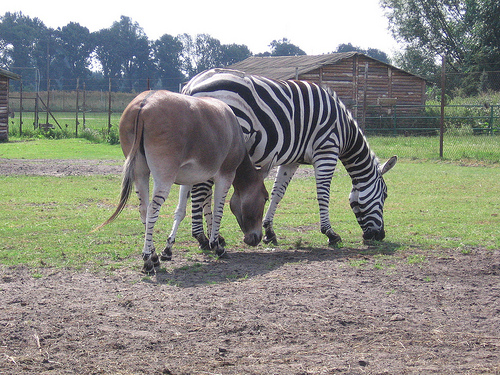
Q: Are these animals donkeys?
A: No, they are donkeys and zebras.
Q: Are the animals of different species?
A: Yes, they are donkeys and zebras.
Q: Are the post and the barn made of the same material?
A: Yes, both the post and the barn are made of wood.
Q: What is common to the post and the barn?
A: The material, both the post and the barn are wooden.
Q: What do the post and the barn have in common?
A: The material, both the post and the barn are wooden.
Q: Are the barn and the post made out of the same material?
A: Yes, both the barn and the post are made of wood.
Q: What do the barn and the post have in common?
A: The material, both the barn and the post are wooden.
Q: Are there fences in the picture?
A: Yes, there is a fence.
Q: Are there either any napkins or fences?
A: Yes, there is a fence.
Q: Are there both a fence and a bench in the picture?
A: No, there is a fence but no benches.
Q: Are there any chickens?
A: No, there are no chickens.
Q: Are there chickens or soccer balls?
A: No, there are no chickens or soccer balls.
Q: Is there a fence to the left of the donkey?
A: Yes, there is a fence to the left of the donkey.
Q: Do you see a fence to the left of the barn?
A: Yes, there is a fence to the left of the barn.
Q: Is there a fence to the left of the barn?
A: Yes, there is a fence to the left of the barn.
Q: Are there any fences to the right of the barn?
A: No, the fence is to the left of the barn.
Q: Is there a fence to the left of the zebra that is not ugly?
A: Yes, there is a fence to the left of the zebra.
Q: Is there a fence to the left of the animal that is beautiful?
A: Yes, there is a fence to the left of the zebra.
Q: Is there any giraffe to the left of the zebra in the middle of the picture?
A: No, there is a fence to the left of the zebra.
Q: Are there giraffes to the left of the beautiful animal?
A: No, there is a fence to the left of the zebra.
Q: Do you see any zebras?
A: Yes, there is a zebra.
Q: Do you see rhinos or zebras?
A: Yes, there is a zebra.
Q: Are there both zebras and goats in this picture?
A: No, there is a zebra but no goats.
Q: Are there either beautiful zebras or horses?
A: Yes, there is a beautiful zebra.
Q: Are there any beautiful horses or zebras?
A: Yes, there is a beautiful zebra.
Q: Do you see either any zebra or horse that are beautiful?
A: Yes, the zebra is beautiful.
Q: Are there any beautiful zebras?
A: Yes, there is a beautiful zebra.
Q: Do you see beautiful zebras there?
A: Yes, there is a beautiful zebra.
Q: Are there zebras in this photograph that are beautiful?
A: Yes, there is a zebra that is beautiful.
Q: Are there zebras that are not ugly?
A: Yes, there is an beautiful zebra.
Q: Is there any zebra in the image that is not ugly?
A: Yes, there is an beautiful zebra.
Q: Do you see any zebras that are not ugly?
A: Yes, there is an beautiful zebra.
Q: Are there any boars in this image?
A: No, there are no boars.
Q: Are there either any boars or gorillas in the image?
A: No, there are no boars or gorillas.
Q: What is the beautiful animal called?
A: The animal is a zebra.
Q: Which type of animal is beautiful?
A: The animal is a zebra.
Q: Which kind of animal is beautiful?
A: The animal is a zebra.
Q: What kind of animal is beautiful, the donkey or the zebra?
A: The zebra is beautiful.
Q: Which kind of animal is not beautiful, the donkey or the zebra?
A: The donkey is not beautiful.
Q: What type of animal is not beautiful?
A: The animal is a donkey.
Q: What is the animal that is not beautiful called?
A: The animal is a donkey.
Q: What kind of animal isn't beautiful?
A: The animal is a donkey.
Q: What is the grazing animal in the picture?
A: The animal is a zebra.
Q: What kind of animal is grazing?
A: The animal is a zebra.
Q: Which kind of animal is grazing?
A: The animal is a zebra.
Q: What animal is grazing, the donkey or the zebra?
A: The zebra is grazing.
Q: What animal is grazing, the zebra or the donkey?
A: The zebra is grazing.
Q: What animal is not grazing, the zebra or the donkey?
A: The donkey is not grazing.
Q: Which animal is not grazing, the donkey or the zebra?
A: The donkey is not grazing.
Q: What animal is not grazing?
A: The animal is a donkey.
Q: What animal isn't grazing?
A: The animal is a donkey.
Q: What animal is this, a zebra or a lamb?
A: This is a zebra.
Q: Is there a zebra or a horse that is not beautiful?
A: No, there is a zebra but it is beautiful.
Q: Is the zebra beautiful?
A: Yes, the zebra is beautiful.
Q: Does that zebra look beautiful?
A: Yes, the zebra is beautiful.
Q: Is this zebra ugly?
A: No, the zebra is beautiful.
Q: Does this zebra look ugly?
A: No, the zebra is beautiful.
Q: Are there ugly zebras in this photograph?
A: No, there is a zebra but it is beautiful.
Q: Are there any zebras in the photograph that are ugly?
A: No, there is a zebra but it is beautiful.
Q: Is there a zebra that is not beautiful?
A: No, there is a zebra but it is beautiful.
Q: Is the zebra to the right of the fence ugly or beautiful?
A: The zebra is beautiful.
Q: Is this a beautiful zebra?
A: Yes, this is a beautiful zebra.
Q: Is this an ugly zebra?
A: No, this is a beautiful zebra.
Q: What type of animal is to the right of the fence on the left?
A: The animal is a zebra.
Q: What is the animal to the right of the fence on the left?
A: The animal is a zebra.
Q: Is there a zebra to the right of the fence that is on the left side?
A: Yes, there is a zebra to the right of the fence.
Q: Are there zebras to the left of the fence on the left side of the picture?
A: No, the zebra is to the right of the fence.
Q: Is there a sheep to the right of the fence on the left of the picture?
A: No, there is a zebra to the right of the fence.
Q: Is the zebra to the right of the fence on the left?
A: Yes, the zebra is to the right of the fence.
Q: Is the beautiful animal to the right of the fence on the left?
A: Yes, the zebra is to the right of the fence.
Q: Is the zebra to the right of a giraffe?
A: No, the zebra is to the right of the fence.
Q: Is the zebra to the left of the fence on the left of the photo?
A: No, the zebra is to the right of the fence.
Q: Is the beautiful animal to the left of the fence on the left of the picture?
A: No, the zebra is to the right of the fence.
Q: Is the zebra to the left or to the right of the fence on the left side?
A: The zebra is to the right of the fence.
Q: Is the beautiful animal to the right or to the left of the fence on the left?
A: The zebra is to the right of the fence.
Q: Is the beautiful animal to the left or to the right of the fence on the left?
A: The zebra is to the right of the fence.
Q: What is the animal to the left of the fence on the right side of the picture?
A: The animal is a zebra.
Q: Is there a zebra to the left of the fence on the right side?
A: Yes, there is a zebra to the left of the fence.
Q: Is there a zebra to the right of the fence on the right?
A: No, the zebra is to the left of the fence.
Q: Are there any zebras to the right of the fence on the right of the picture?
A: No, the zebra is to the left of the fence.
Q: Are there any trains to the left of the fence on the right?
A: No, there is a zebra to the left of the fence.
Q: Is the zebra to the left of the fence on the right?
A: Yes, the zebra is to the left of the fence.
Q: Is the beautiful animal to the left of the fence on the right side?
A: Yes, the zebra is to the left of the fence.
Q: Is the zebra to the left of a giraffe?
A: No, the zebra is to the left of the fence.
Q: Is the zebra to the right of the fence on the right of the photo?
A: No, the zebra is to the left of the fence.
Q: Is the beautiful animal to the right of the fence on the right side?
A: No, the zebra is to the left of the fence.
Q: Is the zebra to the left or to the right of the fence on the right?
A: The zebra is to the left of the fence.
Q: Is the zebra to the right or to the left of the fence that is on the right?
A: The zebra is to the left of the fence.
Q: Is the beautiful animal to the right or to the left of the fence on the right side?
A: The zebra is to the left of the fence.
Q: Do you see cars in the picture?
A: No, there are no cars.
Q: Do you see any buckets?
A: No, there are no buckets.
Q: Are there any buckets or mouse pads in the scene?
A: No, there are no buckets or mouse pads.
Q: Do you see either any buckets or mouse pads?
A: No, there are no buckets or mouse pads.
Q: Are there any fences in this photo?
A: Yes, there is a fence.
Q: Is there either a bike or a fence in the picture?
A: Yes, there is a fence.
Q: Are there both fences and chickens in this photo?
A: No, there is a fence but no chickens.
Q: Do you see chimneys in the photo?
A: No, there are no chimneys.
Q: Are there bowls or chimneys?
A: No, there are no chimneys or bowls.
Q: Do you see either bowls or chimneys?
A: No, there are no chimneys or bowls.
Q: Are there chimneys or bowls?
A: No, there are no chimneys or bowls.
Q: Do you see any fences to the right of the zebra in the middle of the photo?
A: Yes, there is a fence to the right of the zebra.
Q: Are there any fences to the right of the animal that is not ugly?
A: Yes, there is a fence to the right of the zebra.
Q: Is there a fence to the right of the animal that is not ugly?
A: Yes, there is a fence to the right of the zebra.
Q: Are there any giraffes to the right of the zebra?
A: No, there is a fence to the right of the zebra.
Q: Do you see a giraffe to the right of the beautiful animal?
A: No, there is a fence to the right of the zebra.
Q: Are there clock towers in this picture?
A: No, there are no clock towers.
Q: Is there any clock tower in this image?
A: No, there are no clock towers.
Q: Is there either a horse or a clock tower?
A: No, there are no clock towers or horses.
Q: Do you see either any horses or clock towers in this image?
A: No, there are no clock towers or horses.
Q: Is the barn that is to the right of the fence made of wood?
A: Yes, the barn is made of wood.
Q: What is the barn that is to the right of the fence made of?
A: The barn is made of wood.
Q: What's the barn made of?
A: The barn is made of wood.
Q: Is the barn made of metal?
A: No, the barn is made of wood.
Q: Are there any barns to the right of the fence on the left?
A: Yes, there is a barn to the right of the fence.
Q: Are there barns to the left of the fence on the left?
A: No, the barn is to the right of the fence.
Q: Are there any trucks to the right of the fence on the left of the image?
A: No, there is a barn to the right of the fence.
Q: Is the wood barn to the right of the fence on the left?
A: Yes, the barn is to the right of the fence.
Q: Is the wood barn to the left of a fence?
A: No, the barn is to the right of a fence.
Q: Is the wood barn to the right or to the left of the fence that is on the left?
A: The barn is to the right of the fence.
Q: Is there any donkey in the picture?
A: Yes, there is a donkey.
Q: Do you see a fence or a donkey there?
A: Yes, there is a donkey.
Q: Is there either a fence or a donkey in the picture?
A: Yes, there is a donkey.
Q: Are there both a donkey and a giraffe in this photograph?
A: No, there is a donkey but no giraffes.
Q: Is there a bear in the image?
A: No, there are no bears.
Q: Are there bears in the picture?
A: No, there are no bears.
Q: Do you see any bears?
A: No, there are no bears.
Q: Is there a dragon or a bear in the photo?
A: No, there are no bears or dragons.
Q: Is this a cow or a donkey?
A: This is a donkey.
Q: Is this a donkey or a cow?
A: This is a donkey.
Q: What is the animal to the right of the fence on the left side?
A: The animal is a donkey.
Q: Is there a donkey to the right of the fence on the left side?
A: Yes, there is a donkey to the right of the fence.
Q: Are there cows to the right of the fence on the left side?
A: No, there is a donkey to the right of the fence.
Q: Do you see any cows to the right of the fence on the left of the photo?
A: No, there is a donkey to the right of the fence.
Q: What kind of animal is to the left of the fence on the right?
A: The animal is a donkey.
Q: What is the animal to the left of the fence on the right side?
A: The animal is a donkey.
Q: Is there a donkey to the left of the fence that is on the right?
A: Yes, there is a donkey to the left of the fence.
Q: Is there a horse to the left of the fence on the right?
A: No, there is a donkey to the left of the fence.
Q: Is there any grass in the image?
A: Yes, there is grass.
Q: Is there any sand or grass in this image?
A: Yes, there is grass.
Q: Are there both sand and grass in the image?
A: No, there is grass but no sand.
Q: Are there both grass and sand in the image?
A: No, there is grass but no sand.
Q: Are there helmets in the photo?
A: No, there are no helmets.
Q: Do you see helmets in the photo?
A: No, there are no helmets.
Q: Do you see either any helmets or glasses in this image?
A: No, there are no helmets or glasses.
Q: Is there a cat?
A: No, there are no cats.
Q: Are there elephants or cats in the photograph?
A: No, there are no cats or elephants.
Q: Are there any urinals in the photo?
A: No, there are no urinals.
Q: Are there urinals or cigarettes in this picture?
A: No, there are no urinals or cigarettes.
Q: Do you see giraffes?
A: No, there are no giraffes.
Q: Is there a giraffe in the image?
A: No, there are no giraffes.